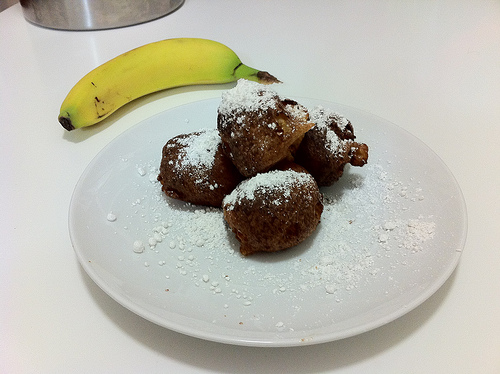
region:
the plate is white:
[302, 320, 309, 330]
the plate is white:
[303, 323, 315, 333]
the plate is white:
[304, 314, 322, 361]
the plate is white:
[304, 298, 319, 332]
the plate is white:
[314, 318, 324, 341]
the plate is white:
[287, 321, 301, 338]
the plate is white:
[322, 307, 333, 335]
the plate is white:
[332, 329, 341, 339]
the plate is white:
[312, 328, 322, 336]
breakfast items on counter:
[77, 27, 459, 345]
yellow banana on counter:
[41, 22, 276, 125]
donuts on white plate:
[185, 99, 315, 253]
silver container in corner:
[21, 0, 183, 37]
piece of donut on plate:
[220, 172, 315, 246]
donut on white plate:
[164, 120, 226, 197]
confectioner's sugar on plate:
[128, 238, 152, 253]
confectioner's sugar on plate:
[104, 209, 129, 226]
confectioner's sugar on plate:
[322, 281, 344, 301]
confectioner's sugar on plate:
[376, 231, 384, 238]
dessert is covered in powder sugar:
[105, 95, 435, 329]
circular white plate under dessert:
[68, 88, 465, 348]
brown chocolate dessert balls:
[162, 93, 367, 246]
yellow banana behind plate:
[58, 38, 279, 128]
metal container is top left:
[19, 1, 185, 30]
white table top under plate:
[1, 1, 499, 373]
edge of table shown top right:
[0, 0, 21, 15]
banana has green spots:
[60, 42, 279, 129]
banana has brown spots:
[85, 73, 131, 118]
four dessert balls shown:
[158, 88, 365, 248]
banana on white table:
[85, 8, 332, 134]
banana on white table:
[39, 30, 203, 135]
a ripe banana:
[54, 27, 276, 132]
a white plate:
[76, 87, 458, 346]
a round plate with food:
[69, 86, 466, 350]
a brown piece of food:
[216, 167, 321, 257]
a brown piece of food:
[163, 128, 239, 206]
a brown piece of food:
[221, 81, 298, 164]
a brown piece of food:
[291, 100, 356, 177]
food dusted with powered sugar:
[161, 87, 359, 251]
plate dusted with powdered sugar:
[118, 156, 432, 309]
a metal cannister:
[18, 0, 188, 38]